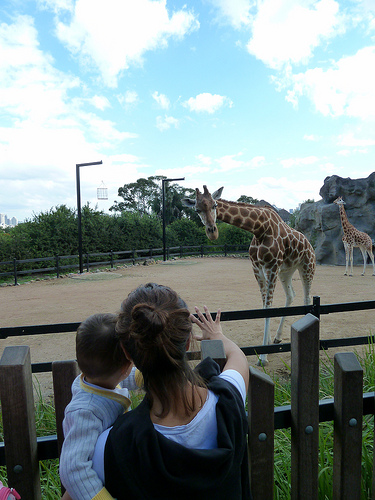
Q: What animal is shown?
A: A giraffe.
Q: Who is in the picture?
A: A woman and baby.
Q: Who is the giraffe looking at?
A: The woman.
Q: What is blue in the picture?
A: The sky.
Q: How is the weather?
A: Sunny and cloudy.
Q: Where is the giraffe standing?
A: Other Side of fence.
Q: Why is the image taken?
A: Remembrance.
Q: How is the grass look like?
A: Green.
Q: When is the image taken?
A: Giraffe standing.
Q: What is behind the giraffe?
A: Stone.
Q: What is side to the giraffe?
A: Poles.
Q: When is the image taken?
A: Evening timings.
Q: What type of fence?
A: Black and wood.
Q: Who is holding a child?
A: A lady.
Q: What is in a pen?
A: A giraffe.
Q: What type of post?
A: Wooden fence.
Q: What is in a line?
A: The bushes.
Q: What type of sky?
A: Blue and white sky.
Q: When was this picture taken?
A: During the day.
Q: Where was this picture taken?
A: AT a zoo.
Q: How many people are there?
A: Two.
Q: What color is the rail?
A: Brown.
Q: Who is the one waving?
A: The adult.